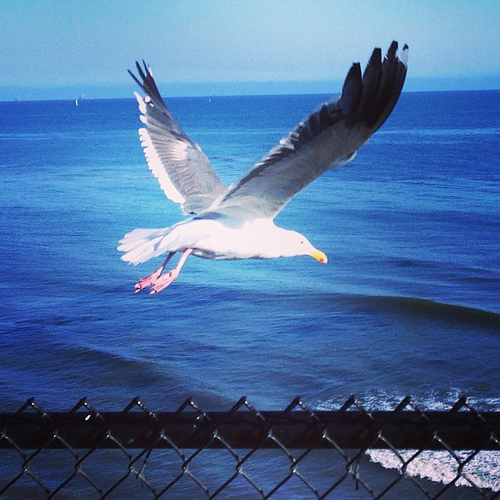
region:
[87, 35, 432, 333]
bird in the sky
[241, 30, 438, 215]
wing of the bird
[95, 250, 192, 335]
legs of the bird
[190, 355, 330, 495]
fence next to bird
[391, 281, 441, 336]
wave in the water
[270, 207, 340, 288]
head of the bird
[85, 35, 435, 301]
white bird above water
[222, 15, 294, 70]
sky in the background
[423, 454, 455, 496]
white water below bird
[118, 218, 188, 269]
tail feathers of the bird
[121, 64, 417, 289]
A bird above the water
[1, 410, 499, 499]
A fence behind the bird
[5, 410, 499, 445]
A black railing connected to the fence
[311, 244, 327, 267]
The beak of the bird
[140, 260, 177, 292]
The feet of the bird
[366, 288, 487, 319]
Small waves on the water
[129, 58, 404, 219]
The wings of the bird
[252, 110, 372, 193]
Black and white feathers on the bird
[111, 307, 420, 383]
Blue water below the fence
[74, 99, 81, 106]
A boat far from the bird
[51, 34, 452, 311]
A white color bird flying in the air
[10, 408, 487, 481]
A metal rod with fencing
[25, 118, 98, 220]
A blue color sea water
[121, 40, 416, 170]
Long narrow wings of the bird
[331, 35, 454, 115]
Wing slots of the bird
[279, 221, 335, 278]
Head of the bird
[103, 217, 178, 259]
Tail of the bird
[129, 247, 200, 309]
Legs of the bird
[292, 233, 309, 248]
Eye of the bird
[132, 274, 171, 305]
Feet of the bird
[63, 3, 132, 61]
this is the sky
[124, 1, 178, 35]
the sky is blue in color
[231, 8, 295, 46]
the sky has some clouds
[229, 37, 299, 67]
the clouds are white in color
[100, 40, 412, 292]
this is a bird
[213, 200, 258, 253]
the feathers are white in color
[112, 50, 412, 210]
the wings are open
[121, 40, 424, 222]
the wings are big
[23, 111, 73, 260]
this is the water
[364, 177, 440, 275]
the water is blue in color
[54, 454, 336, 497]
this is a fence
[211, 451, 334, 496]
this is wire mess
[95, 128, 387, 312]
this is a bird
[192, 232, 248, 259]
the bird is white in color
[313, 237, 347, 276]
this is the beak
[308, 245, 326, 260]
the beak is yellow in color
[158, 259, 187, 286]
this is the leg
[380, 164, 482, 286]
this is a water body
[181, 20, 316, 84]
this is the sky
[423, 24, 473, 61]
the sky is blue in color